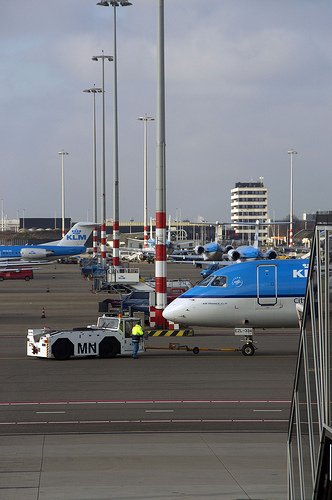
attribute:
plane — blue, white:
[143, 223, 320, 348]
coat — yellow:
[119, 317, 155, 336]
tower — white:
[230, 177, 271, 242]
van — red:
[4, 258, 36, 281]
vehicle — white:
[32, 310, 152, 361]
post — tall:
[158, 3, 172, 326]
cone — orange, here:
[34, 301, 54, 322]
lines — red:
[56, 397, 190, 423]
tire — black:
[231, 339, 259, 357]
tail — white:
[61, 220, 99, 248]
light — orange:
[110, 312, 131, 323]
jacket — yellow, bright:
[126, 319, 143, 336]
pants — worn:
[130, 342, 143, 360]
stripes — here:
[15, 387, 264, 436]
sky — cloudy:
[180, 10, 316, 128]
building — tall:
[215, 169, 277, 241]